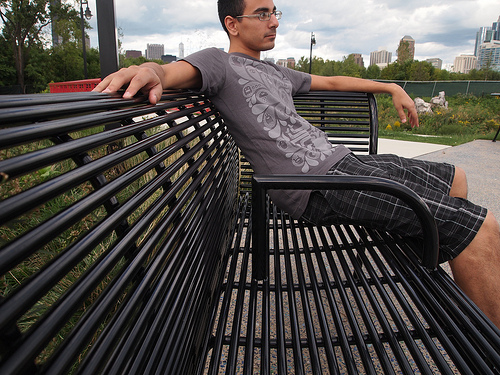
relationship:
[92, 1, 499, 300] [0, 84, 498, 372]
man sitting on bench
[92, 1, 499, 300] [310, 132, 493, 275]
man wearing shorts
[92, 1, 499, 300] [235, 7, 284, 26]
man wearing glasses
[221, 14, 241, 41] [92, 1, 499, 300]
ear of man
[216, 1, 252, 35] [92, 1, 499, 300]
hair of man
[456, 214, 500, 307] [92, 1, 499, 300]
leg of man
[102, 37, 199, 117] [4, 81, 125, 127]
arm resting pipe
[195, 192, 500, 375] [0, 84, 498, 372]
bottom on bench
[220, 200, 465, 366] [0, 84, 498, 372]
bottom on bench